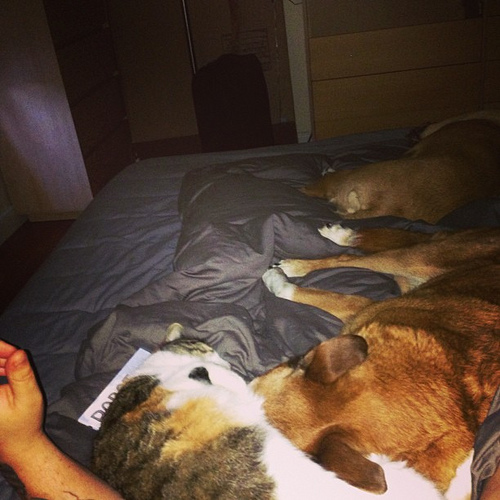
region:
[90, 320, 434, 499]
sleeping cat on bed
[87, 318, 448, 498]
striped cat sleeping on bed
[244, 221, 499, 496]
brown dog on bed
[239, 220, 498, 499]
brown dog sleeping near cat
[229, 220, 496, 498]
dog with face on cat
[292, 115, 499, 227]
sleeping dog in background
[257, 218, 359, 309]
white paws on sleeping dog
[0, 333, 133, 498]
left hand of white person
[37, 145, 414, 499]
gray blanket on bed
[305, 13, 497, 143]
wood panels on wall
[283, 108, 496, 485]
two dogs laying on a bed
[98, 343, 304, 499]
a cat laying on a bed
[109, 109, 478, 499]
several animals sleeping on a bed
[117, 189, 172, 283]
blue comforter on the bed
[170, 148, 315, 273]
grey pillow on the bed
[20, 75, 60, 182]
tan wood of the dresser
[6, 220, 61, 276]
brown carpet floor of the room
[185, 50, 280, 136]
a black suitcase on the floor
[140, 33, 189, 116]
white wall of the bedroom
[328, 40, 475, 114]
tan wood panels on the wall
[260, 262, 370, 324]
the brown and white leg of the dog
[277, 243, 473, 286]
the brown and white leg of the dog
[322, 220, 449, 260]
the brown and white leg of the dog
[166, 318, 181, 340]
the ear of the cat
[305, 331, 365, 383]
the brown ear of the dog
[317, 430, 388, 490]
the brown ear of the dog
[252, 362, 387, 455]
the head of the dog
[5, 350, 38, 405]
the thumb of the hand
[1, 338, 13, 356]
the finger of the hand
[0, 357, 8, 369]
the finger of the hand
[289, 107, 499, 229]
dog laying on bed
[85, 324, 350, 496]
cat laying on bed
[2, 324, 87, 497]
an arm of a person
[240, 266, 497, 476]
dog laying on bed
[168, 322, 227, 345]
ears of a cat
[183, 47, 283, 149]
a luggage of some sort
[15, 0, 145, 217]
a shelf on a floor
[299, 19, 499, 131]
a long shelf behind bed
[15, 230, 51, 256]
a dark carpet flooring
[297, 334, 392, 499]
ears of a dog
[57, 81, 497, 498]
three animals on the bed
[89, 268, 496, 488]
a cat and dog sleeping together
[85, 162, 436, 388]
a gray blanket on bed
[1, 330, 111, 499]
a human hand and arm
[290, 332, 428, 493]
brown ears of a dog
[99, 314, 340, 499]
a multi colored cat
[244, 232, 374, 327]
white paws on the dog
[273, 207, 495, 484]
a brown dog sleeping by cat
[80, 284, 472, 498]
a cat and dog cuddling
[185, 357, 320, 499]
white belly of cat